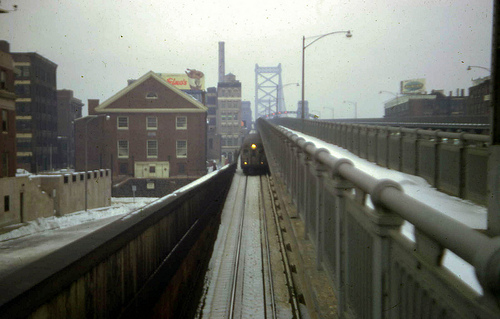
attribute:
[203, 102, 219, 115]
window — glass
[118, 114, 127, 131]
window — is glass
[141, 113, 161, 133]
window — is glass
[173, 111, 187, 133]
window — is glass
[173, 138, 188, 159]
window — is glass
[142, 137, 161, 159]
window — is glass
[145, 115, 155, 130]
window — glass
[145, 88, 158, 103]
window — is glass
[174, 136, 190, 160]
window — glass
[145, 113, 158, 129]
window — is glass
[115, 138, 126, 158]
window — is glass